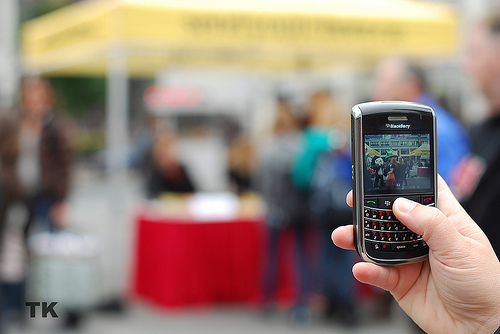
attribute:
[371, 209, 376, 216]
number — red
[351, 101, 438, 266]
phone — black, clear, blackberry, smartphone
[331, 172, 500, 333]
hand — white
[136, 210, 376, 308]
table — red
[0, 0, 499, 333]
background — blurry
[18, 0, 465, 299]
tent — yellow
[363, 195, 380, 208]
button — green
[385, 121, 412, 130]
letters — white